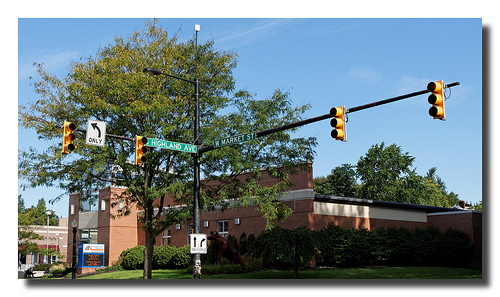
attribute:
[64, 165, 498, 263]
building — light brown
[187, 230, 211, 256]
sign — white and black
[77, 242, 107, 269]
sign — electronic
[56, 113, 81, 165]
lights — yellow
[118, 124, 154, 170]
lights — yellow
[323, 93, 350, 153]
lights — yellow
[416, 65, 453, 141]
lights — yellow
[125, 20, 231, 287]
light post — metal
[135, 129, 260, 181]
street sign — green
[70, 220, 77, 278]
street-lamp — black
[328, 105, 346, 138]
traffic signal — yellow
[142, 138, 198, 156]
street sign — green, white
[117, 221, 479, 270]
shrubs — green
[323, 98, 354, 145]
traffic signal — yellow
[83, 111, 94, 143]
sign — white, Black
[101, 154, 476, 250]
building — bricked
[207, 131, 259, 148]
sign — green 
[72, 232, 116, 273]
sign — digital